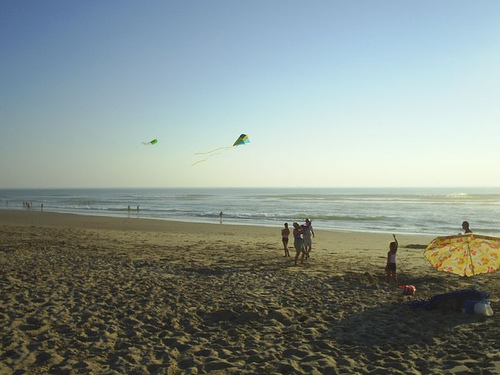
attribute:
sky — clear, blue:
[7, 14, 485, 121]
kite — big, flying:
[231, 131, 251, 147]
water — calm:
[0, 187, 500, 238]